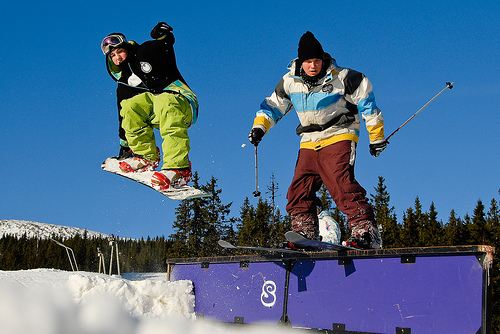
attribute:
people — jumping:
[99, 22, 385, 254]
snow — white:
[2, 268, 235, 333]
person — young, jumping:
[99, 22, 198, 191]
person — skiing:
[250, 29, 384, 250]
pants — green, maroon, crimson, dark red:
[120, 80, 199, 170]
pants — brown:
[286, 140, 380, 239]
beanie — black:
[297, 31, 325, 64]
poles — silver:
[384, 80, 452, 141]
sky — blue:
[2, 1, 497, 243]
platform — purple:
[164, 244, 494, 332]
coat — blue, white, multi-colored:
[250, 52, 387, 147]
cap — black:
[298, 32, 323, 66]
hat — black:
[298, 31, 325, 63]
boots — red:
[150, 168, 192, 191]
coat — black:
[118, 34, 183, 146]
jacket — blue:
[250, 52, 387, 148]